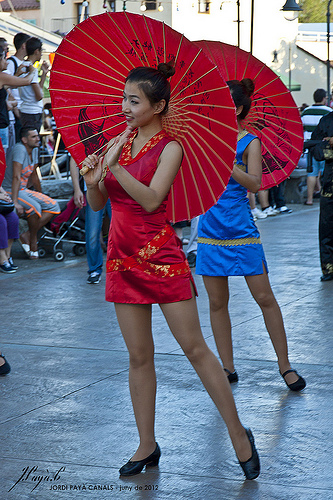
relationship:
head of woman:
[118, 65, 178, 127] [85, 52, 196, 337]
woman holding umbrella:
[82, 63, 261, 481] [48, 9, 236, 222]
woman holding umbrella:
[82, 63, 261, 481] [190, 38, 304, 190]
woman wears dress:
[187, 68, 310, 397] [188, 126, 270, 278]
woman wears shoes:
[82, 63, 261, 481] [96, 420, 296, 496]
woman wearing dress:
[86, 61, 208, 288] [94, 130, 201, 287]